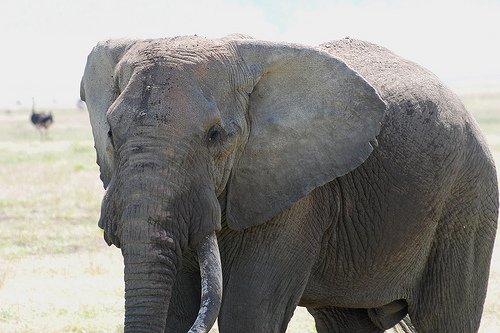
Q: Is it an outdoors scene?
A: Yes, it is outdoors.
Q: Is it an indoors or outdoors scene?
A: It is outdoors.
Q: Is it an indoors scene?
A: No, it is outdoors.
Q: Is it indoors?
A: No, it is outdoors.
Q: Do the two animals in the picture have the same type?
A: No, they are elephants and ostriches.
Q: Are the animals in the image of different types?
A: Yes, they are elephants and ostriches.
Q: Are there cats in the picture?
A: No, there are no cats.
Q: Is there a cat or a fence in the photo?
A: No, there are no cats or fences.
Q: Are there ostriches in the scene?
A: Yes, there is an ostrich.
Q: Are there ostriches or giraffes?
A: Yes, there is an ostrich.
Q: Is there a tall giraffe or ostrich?
A: Yes, there is a tall ostrich.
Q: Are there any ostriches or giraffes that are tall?
A: Yes, the ostrich is tall.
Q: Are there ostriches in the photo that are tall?
A: Yes, there is a tall ostrich.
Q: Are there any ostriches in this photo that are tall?
A: Yes, there is an ostrich that is tall.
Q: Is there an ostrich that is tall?
A: Yes, there is an ostrich that is tall.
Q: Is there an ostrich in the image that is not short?
A: Yes, there is a tall ostrich.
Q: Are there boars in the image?
A: No, there are no boars.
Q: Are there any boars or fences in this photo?
A: No, there are no boars or fences.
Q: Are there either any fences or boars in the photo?
A: No, there are no boars or fences.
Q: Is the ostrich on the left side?
A: Yes, the ostrich is on the left of the image.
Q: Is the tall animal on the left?
A: Yes, the ostrich is on the left of the image.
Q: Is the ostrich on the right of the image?
A: No, the ostrich is on the left of the image.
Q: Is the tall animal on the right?
A: No, the ostrich is on the left of the image.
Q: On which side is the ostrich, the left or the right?
A: The ostrich is on the left of the image.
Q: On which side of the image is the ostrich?
A: The ostrich is on the left of the image.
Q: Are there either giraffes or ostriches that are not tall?
A: No, there is an ostrich but it is tall.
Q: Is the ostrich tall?
A: Yes, the ostrich is tall.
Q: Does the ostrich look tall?
A: Yes, the ostrich is tall.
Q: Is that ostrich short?
A: No, the ostrich is tall.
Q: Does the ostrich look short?
A: No, the ostrich is tall.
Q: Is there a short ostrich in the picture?
A: No, there is an ostrich but it is tall.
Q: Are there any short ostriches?
A: No, there is an ostrich but it is tall.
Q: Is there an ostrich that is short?
A: No, there is an ostrich but it is tall.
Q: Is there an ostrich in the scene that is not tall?
A: No, there is an ostrich but it is tall.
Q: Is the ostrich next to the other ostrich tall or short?
A: The ostrich is tall.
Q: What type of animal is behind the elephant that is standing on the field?
A: The animal is an ostrich.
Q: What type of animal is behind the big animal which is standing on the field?
A: The animal is an ostrich.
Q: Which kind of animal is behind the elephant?
A: The animal is an ostrich.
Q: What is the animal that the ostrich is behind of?
A: The animal is an elephant.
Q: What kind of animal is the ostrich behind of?
A: The ostrich is behind the elephant.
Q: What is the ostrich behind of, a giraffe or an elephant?
A: The ostrich is behind an elephant.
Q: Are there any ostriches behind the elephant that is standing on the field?
A: Yes, there is an ostrich behind the elephant.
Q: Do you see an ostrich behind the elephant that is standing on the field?
A: Yes, there is an ostrich behind the elephant.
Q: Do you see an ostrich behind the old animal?
A: Yes, there is an ostrich behind the elephant.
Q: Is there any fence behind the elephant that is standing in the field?
A: No, there is an ostrich behind the elephant.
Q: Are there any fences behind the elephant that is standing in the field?
A: No, there is an ostrich behind the elephant.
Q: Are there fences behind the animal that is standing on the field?
A: No, there is an ostrich behind the elephant.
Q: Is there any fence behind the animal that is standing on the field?
A: No, there is an ostrich behind the elephant.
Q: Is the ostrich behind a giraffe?
A: No, the ostrich is behind the elephant.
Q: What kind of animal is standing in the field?
A: The animal is an ostrich.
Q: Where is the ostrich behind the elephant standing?
A: The ostrich is standing in the field.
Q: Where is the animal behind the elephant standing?
A: The ostrich is standing in the field.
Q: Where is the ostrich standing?
A: The ostrich is standing in the field.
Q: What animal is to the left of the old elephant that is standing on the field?
A: The animal is an ostrich.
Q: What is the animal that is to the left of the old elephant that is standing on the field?
A: The animal is an ostrich.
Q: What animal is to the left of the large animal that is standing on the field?
A: The animal is an ostrich.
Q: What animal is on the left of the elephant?
A: The animal is an ostrich.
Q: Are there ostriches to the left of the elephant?
A: Yes, there is an ostrich to the left of the elephant.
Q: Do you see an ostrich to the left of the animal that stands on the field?
A: Yes, there is an ostrich to the left of the elephant.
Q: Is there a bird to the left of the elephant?
A: No, there is an ostrich to the left of the elephant.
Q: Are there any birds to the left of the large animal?
A: No, there is an ostrich to the left of the elephant.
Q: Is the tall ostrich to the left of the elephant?
A: Yes, the ostrich is to the left of the elephant.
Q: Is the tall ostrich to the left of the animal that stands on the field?
A: Yes, the ostrich is to the left of the elephant.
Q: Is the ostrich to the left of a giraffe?
A: No, the ostrich is to the left of the elephant.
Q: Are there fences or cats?
A: No, there are no fences or cats.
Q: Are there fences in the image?
A: No, there are no fences.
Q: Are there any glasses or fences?
A: No, there are no fences or glasses.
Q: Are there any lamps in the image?
A: No, there are no lamps.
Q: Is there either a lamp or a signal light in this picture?
A: No, there are no lamps or traffic lights.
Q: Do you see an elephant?
A: Yes, there is an elephant.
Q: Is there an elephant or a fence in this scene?
A: Yes, there is an elephant.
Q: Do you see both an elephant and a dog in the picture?
A: No, there is an elephant but no dogs.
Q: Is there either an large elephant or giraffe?
A: Yes, there is a large elephant.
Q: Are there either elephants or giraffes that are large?
A: Yes, the elephant is large.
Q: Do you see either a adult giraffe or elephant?
A: Yes, there is an adult elephant.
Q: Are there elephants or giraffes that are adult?
A: Yes, the elephant is adult.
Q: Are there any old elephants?
A: Yes, there is an old elephant.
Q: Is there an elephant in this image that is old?
A: Yes, there is an elephant that is old.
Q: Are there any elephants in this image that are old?
A: Yes, there is an elephant that is old.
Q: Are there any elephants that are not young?
A: Yes, there is a old elephant.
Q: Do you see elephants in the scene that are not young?
A: Yes, there is a old elephant.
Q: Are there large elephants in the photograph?
A: Yes, there is a large elephant.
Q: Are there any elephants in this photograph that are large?
A: Yes, there is an elephant that is large.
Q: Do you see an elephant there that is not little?
A: Yes, there is a large elephant.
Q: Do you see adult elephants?
A: Yes, there is an adult elephant.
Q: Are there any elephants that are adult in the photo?
A: Yes, there is an adult elephant.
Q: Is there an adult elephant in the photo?
A: Yes, there is an adult elephant.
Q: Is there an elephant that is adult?
A: Yes, there is an elephant that is adult.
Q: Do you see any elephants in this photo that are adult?
A: Yes, there is an elephant that is adult.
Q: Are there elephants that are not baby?
A: Yes, there is a adult elephant.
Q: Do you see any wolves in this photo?
A: No, there are no wolves.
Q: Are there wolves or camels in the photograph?
A: No, there are no wolves or camels.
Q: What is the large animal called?
A: The animal is an elephant.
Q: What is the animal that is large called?
A: The animal is an elephant.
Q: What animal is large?
A: The animal is an elephant.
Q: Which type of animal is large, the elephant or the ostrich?
A: The elephant is large.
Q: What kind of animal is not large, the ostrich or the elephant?
A: The ostrich is not large.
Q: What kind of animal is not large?
A: The animal is an ostrich.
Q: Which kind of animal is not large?
A: The animal is an ostrich.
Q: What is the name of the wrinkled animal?
A: The animal is an elephant.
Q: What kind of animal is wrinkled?
A: The animal is an elephant.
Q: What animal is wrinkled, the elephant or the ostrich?
A: The elephant is wrinkled.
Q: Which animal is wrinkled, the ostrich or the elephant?
A: The elephant is wrinkled.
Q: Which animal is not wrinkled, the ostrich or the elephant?
A: The ostrich is not wrinkled.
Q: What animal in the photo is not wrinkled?
A: The animal is an ostrich.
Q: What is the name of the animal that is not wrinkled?
A: The animal is an ostrich.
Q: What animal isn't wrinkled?
A: The animal is an ostrich.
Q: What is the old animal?
A: The animal is an elephant.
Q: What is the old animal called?
A: The animal is an elephant.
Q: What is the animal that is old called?
A: The animal is an elephant.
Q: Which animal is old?
A: The animal is an elephant.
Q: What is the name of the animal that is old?
A: The animal is an elephant.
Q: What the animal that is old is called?
A: The animal is an elephant.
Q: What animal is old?
A: The animal is an elephant.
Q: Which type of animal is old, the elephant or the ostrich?
A: The elephant is old.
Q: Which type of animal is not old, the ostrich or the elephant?
A: The ostrich is not old.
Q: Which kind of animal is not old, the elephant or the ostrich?
A: The ostrich is not old.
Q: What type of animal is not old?
A: The animal is an ostrich.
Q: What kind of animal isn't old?
A: The animal is an ostrich.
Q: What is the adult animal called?
A: The animal is an elephant.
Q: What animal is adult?
A: The animal is an elephant.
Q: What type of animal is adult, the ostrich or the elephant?
A: The elephant is adult.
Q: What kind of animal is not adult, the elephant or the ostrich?
A: The ostrich is not adult.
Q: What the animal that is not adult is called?
A: The animal is an ostrich.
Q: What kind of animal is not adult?
A: The animal is an ostrich.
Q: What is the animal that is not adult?
A: The animal is an ostrich.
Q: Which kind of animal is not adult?
A: The animal is an ostrich.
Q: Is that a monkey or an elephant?
A: That is an elephant.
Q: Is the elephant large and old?
A: Yes, the elephant is large and old.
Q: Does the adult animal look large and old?
A: Yes, the elephant is large and old.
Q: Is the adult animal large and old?
A: Yes, the elephant is large and old.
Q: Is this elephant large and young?
A: No, the elephant is large but old.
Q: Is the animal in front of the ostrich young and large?
A: No, the elephant is large but old.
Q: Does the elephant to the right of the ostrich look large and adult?
A: Yes, the elephant is large and adult.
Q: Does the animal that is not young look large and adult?
A: Yes, the elephant is large and adult.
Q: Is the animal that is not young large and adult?
A: Yes, the elephant is large and adult.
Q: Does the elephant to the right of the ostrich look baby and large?
A: No, the elephant is large but adult.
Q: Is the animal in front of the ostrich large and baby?
A: No, the elephant is large but adult.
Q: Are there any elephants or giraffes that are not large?
A: No, there is an elephant but it is large.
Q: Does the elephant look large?
A: Yes, the elephant is large.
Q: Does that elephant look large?
A: Yes, the elephant is large.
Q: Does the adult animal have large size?
A: Yes, the elephant is large.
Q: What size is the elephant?
A: The elephant is large.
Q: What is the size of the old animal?
A: The elephant is large.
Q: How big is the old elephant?
A: The elephant is large.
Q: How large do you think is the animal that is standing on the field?
A: The elephant is large.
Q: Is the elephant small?
A: No, the elephant is large.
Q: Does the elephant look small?
A: No, the elephant is large.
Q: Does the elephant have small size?
A: No, the elephant is large.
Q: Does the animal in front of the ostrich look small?
A: No, the elephant is large.